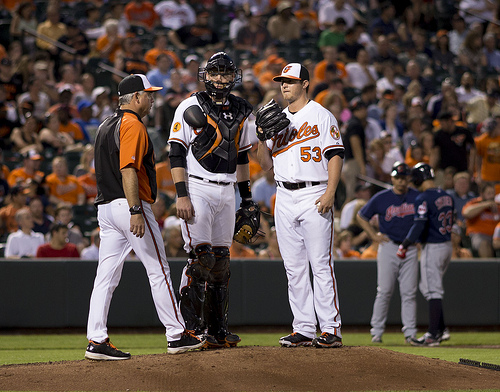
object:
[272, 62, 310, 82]
cap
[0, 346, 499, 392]
mound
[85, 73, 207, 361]
man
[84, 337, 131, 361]
shoe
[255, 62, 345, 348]
man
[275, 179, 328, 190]
belt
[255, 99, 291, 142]
glove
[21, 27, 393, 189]
pole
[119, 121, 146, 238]
arm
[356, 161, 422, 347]
man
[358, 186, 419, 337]
uniform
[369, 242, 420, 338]
pants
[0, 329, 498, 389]
field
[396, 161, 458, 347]
player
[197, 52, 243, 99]
face mask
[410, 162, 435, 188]
helmet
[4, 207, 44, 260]
fan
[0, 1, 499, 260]
stands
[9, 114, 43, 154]
fan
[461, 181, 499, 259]
fan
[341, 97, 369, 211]
fan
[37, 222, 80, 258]
fan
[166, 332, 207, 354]
shoe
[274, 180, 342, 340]
pants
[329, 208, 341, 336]
stripe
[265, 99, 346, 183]
shirt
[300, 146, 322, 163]
53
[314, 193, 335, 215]
hand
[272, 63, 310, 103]
head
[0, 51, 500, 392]
game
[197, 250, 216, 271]
knee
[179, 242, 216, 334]
protection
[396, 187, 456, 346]
uniform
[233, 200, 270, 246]
mitt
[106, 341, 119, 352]
shoelaces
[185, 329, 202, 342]
shoelaces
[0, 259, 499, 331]
fence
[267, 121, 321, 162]
orioles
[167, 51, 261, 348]
gear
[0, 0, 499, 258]
crowd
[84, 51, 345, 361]
team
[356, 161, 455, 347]
team